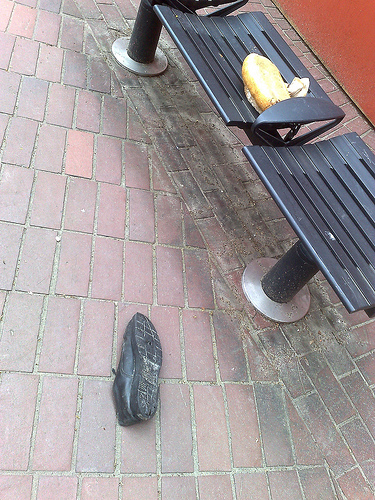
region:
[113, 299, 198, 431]
black shoe on brick road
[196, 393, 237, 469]
red brick on road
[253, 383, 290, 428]
black brick on road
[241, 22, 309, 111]
food left on topp of park bench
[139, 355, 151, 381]
dirt in the middle of a shoe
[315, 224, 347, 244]
bird poop on top of bench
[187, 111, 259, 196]
brown dirt on bricks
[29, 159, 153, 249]
lines on the ground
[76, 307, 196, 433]
shoe on the ground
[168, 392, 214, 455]
one gray line on ground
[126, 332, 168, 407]
bottom of the shoe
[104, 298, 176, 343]
front of the shoe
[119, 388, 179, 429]
back of the shoe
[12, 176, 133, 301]
rectangular ground in photo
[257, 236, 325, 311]
pole under the bench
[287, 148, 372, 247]
sitting part of bench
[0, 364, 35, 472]
red brick in ground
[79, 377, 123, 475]
red brick in ground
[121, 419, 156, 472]
red brick in ground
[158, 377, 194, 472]
red brick in ground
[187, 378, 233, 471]
red brick in ground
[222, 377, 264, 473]
red brick in ground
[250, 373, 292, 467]
red brick in ground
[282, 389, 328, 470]
red brick in ground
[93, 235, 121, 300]
red brick in ground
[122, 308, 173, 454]
A black shoe on the sidewalk.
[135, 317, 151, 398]
Dirt on the bottom of the shoe.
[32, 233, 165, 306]
The floor is bricked.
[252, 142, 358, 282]
A bench on the sidewalk.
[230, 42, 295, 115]
Trash on the bench.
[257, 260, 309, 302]
The legs of the bench is black.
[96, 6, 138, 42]
The ground has a cracked brick.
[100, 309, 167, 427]
The shoe is upside down.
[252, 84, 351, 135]
The arm of the bench.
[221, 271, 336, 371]
Dirt under the bench.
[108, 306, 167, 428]
SHOE ON THE GROUND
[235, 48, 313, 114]
SANDWICH ON THE BENCH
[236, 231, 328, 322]
METAL POST HOLDING BENCH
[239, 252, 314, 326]
SILVER PLATE AROUND POST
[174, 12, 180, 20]
YELLOW CRUMB ON BENCH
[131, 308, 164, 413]
SOLE OF SHOE IS DIRTY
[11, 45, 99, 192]
BRICK INLAY FOR SIDEWALK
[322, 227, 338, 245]
BIRD POOP ON BENCH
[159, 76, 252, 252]
BRICKS UNDER BENCH ARE DIRTY